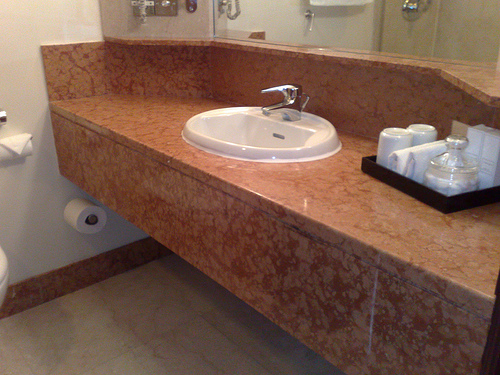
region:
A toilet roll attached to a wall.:
[62, 197, 110, 237]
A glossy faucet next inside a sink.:
[248, 78, 322, 125]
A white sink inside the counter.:
[182, 106, 343, 157]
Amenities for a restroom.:
[375, 127, 494, 193]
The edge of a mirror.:
[95, 0, 260, 43]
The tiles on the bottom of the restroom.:
[33, 275, 217, 374]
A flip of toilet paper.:
[0, 130, 38, 167]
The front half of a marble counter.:
[228, 246, 498, 374]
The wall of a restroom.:
[17, 160, 58, 274]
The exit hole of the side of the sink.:
[267, 126, 292, 146]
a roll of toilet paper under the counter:
[63, 199, 107, 234]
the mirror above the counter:
[98, 1, 499, 65]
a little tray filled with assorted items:
[363, 115, 498, 211]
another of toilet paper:
[1, 130, 38, 165]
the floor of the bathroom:
[0, 272, 335, 374]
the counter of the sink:
[42, 31, 499, 307]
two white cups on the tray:
[373, 120, 430, 169]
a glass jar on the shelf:
[423, 132, 479, 194]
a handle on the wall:
[300, 7, 315, 35]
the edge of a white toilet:
[1, 245, 12, 299]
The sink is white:
[163, 85, 320, 183]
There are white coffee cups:
[357, 120, 490, 240]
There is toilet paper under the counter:
[45, 160, 120, 263]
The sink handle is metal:
[259, 72, 304, 153]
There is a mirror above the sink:
[272, 4, 499, 130]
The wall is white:
[17, 29, 117, 186]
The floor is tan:
[30, 232, 167, 373]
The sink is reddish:
[111, 100, 346, 285]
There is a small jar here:
[422, 121, 497, 244]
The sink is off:
[231, 80, 341, 186]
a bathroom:
[6, 2, 498, 370]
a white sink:
[184, 81, 344, 159]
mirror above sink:
[102, 2, 499, 60]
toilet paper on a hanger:
[65, 195, 106, 236]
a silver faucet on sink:
[259, 82, 303, 119]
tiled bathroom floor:
[24, 295, 236, 367]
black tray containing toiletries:
[369, 112, 499, 206]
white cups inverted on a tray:
[382, 125, 436, 162]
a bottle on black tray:
[430, 120, 472, 186]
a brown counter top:
[40, 50, 495, 280]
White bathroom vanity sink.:
[177, 60, 349, 177]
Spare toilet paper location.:
[52, 192, 117, 243]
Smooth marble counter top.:
[43, 42, 489, 299]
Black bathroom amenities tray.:
[378, 114, 498, 210]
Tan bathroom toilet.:
[0, 208, 35, 315]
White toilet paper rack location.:
[0, 112, 45, 189]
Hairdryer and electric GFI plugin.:
[121, 0, 173, 29]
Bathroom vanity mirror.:
[215, 0, 499, 67]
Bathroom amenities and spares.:
[376, 115, 494, 180]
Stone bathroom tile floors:
[11, 262, 249, 373]